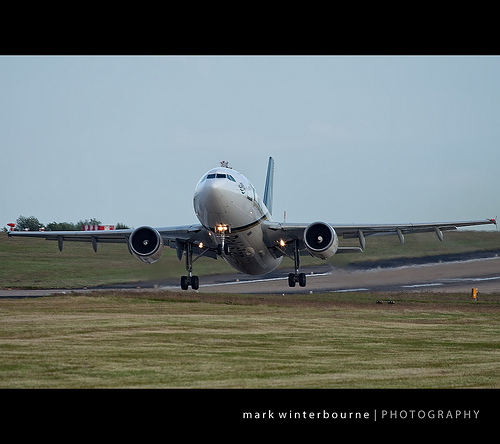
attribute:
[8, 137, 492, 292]
plane — white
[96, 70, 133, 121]
sky — blue, cloudy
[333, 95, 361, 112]
cloud — whtie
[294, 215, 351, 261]
engine — white, large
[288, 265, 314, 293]
wheel — black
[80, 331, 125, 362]
grass — short, brown, yellow